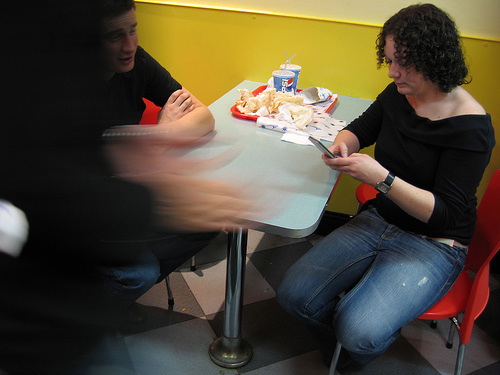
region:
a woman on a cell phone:
[286, 10, 493, 373]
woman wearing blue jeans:
[267, 9, 496, 371]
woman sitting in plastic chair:
[287, 5, 497, 374]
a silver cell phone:
[307, 136, 342, 157]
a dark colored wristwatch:
[374, 168, 396, 192]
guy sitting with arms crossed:
[89, 1, 214, 151]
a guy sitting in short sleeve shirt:
[82, 0, 214, 142]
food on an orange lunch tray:
[239, 64, 339, 129]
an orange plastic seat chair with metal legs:
[428, 169, 499, 369]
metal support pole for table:
[212, 224, 253, 363]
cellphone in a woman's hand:
[308, 134, 339, 162]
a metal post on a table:
[209, 227, 260, 368]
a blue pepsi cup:
[272, 69, 292, 93]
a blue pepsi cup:
[282, 62, 299, 88]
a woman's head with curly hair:
[372, 6, 471, 101]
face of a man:
[104, 8, 139, 73]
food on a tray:
[230, 85, 317, 125]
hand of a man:
[157, 89, 192, 130]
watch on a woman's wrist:
[375, 172, 396, 194]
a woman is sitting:
[277, 4, 494, 361]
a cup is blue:
[273, 68, 293, 90]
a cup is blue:
[282, 62, 300, 93]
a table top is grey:
[162, 79, 371, 233]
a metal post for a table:
[202, 223, 257, 364]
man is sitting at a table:
[98, 1, 211, 328]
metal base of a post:
[210, 334, 252, 367]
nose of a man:
[122, 35, 134, 52]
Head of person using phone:
[380, 1, 472, 99]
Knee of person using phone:
[330, 301, 402, 362]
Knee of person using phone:
[276, 277, 324, 327]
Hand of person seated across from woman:
[151, 88, 198, 120]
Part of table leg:
[213, 245, 258, 370]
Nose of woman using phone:
[385, 64, 400, 78]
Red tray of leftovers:
[232, 58, 343, 123]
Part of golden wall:
[168, 34, 233, 59]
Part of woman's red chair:
[474, 283, 482, 320]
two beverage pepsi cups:
[275, 58, 300, 93]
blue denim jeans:
[284, 210, 476, 370]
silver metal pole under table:
[208, 210, 252, 370]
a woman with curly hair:
[363, 2, 477, 100]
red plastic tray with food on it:
[220, 56, 345, 138]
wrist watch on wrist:
[366, 169, 401, 197]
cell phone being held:
[308, 126, 345, 170]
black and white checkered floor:
[106, 236, 318, 374]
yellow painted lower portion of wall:
[208, 17, 350, 55]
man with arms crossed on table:
[84, 0, 226, 155]